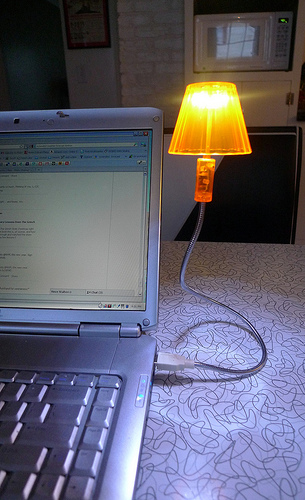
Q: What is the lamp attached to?
A: Computer.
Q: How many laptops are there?
A: One.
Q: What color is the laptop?
A: Silver.